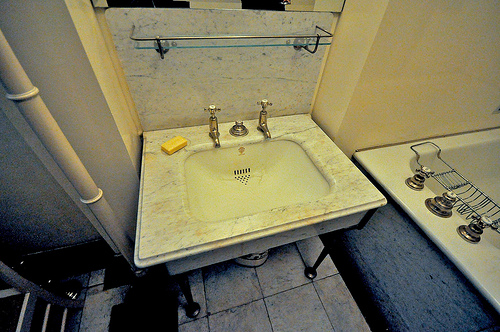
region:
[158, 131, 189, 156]
yellow bar of soap on the sink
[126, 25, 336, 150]
glass shelf above the bathroom sink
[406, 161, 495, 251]
silver and white faucets on the bathtub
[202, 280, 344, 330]
tiled bathroom floor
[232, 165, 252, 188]
holes in the sink that drain water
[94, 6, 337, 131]
marble backsplash above the bathroom sink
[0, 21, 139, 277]
white bathroom pipe near the wall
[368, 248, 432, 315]
marble on the side of the bathtub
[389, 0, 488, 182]
white wall above the bathtub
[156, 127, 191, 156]
soap sitting on the countertop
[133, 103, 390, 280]
White marble bathroom sink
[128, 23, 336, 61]
Glass and metal wall rack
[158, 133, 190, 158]
Yellow bar of soap on bathroom sink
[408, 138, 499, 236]
Metal bathtub rack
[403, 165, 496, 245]
Bathtub faucet knobs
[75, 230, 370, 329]
Marble tiled bathroom flooring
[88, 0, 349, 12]
Bottom edge of a bathroom vanity mirror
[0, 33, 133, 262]
Piping going up a bathroom wall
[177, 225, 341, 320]
Metal legs of a bathroom sink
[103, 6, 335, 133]
White marble backsplash of bathroom sink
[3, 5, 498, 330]
this is a bathroom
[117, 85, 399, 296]
this is a sink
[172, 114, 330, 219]
the sink is white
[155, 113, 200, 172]
a bar of soap on counter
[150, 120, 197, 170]
bar of soap is yellow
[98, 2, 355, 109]
this is a towel rack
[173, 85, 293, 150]
faucet on the sink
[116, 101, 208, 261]
counter top of the sink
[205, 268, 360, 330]
tile on the floor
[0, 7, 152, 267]
pipe next to the sink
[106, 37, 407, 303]
granite sink in bathroom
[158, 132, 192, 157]
yellow bar of soap on sink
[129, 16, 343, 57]
metal towel rack on wall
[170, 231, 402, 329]
white tiles on floor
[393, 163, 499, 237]
metal faucets on tub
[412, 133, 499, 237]
metal soap dish on tub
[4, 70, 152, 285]
pipe along bathroom wall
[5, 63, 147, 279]
piping painted white in bathroom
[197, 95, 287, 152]
metal faucets on sink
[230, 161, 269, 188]
drain in sink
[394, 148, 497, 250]
tree silver taps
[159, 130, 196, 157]
yellow bar of soap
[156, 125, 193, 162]
soap on the corner of the sink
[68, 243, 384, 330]
tile on the floor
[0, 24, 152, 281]
pipe running along the wall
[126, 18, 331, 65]
metal bars attached to the wall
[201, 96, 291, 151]
two silver taps on the sink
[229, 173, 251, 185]
holes in a triangle formation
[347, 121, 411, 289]
corner of the tub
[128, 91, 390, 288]
sink attached to the wall